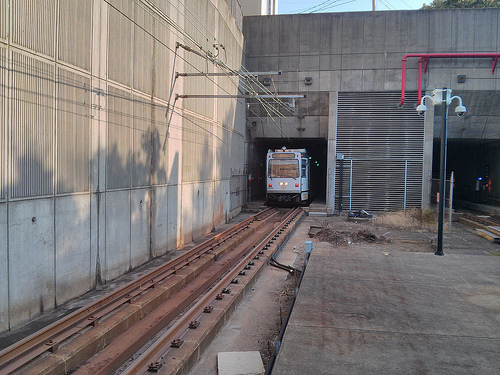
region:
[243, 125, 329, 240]
the train on the tracks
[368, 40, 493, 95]
the pipes in the wall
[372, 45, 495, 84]
the pipes are magenta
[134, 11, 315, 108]
the power cables above the tracks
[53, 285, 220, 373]
the tracks are rusty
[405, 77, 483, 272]
the security cameras the tracks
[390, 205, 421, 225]
the grass is dry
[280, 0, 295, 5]
the clear blue sky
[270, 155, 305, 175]
the windshield of the train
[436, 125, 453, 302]
the black pole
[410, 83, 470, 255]
Black and white lamp pole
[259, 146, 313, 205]
Silver train coming out of the tunnel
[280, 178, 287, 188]
Yellow lights on the front of the train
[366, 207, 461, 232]
Patch of tan grass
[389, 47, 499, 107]
Red poles above tunnel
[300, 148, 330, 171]
Green lights in the tunnel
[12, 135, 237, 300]
Shadows on the wall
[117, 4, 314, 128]
Wires above the train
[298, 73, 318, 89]
Gray hole in wall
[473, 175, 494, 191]
Blue and red lights in tunnel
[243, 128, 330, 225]
the train inside the tunel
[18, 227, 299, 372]
the only train rail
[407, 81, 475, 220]
security camera system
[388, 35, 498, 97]
a pair of red pipes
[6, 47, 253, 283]
concrete train station wall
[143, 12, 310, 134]
electrical cable train system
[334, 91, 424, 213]
metal sliding door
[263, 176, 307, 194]
train signal lights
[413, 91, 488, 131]
a pair of cameras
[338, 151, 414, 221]
a couple of blue pipes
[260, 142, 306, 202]
train is in tunnel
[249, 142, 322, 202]
train is light blue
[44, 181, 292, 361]
tracks are rust colored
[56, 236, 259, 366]
rails in between tracks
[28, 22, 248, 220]
wall beside train is grey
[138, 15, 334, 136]
power wires over train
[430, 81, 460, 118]
white lights on top of poles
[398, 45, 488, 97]
red pipes over tunnels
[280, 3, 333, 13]
sky outside tunnel is blue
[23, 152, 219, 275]
shadows on side of tunnel wall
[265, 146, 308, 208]
front end of a train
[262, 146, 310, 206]
a blue train engine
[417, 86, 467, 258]
white lights on a metal pole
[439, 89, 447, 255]
a grey metal pole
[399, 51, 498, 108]
a series of red pipes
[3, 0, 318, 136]
electric lines for a train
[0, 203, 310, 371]
rusty metal train tracks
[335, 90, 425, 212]
a large metal door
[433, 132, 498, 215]
a darkened tunnel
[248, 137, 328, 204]
train coming from a tunnel